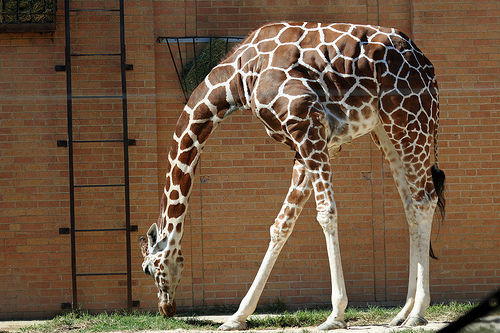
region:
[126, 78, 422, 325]
tall giraffe bending over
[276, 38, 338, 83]
brown and white spots on giraffe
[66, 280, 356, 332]
short green grass on ground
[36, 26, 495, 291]
red brick wall near giraffe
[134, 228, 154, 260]
small horns on head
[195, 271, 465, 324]
white hoofs on giraffe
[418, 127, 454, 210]
bushy black tail on giraffe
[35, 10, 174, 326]
metal ladder attached to wall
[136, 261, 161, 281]
small dark eye of giraffe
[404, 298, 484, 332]
dark object on foreground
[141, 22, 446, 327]
giraffe bending down eating the grass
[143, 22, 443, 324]
a brown and tan giraffe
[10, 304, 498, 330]
grass on the ground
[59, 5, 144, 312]
a black metal ladder on the wall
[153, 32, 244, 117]
a black feeder on the wall with grass in it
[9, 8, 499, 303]
a brick wall behind the giraffe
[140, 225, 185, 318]
the giraffe's head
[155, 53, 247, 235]
the girafffe's long neck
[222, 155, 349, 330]
the giraffe's two front legs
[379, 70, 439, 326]
the giraffe's two hind legs.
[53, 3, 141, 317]
Black iron ladder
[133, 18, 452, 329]
Brown and white giraffe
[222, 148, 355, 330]
Two front giraffe legs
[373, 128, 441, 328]
Back legs of a giraffe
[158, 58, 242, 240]
A giraffe's long neck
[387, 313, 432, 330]
Hooves of a giraffe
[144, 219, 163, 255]
Ear of a giraffe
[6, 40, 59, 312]
Red brick wall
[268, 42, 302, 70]
Brown spot on a giraffe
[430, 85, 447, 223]
Tail of a giraffe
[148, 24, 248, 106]
a giraffe feeder on a wall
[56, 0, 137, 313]
a black ladder on the side of a giraffe pen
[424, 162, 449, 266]
black hair at the end of a giraffe tail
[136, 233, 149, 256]
a black tipped horn on a giraffe head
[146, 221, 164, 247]
the ear of a giraffe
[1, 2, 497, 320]
a red brick wall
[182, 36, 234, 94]
green hay in a giraffe feeder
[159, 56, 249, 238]
the long neck of a giraffe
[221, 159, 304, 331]
a front leg extended forward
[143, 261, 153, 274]
the eye of a giraffe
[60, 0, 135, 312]
A black metal ladder on the wal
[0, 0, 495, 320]
A large brick wall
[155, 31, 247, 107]
A small basket on the wall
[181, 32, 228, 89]
some grass in the basket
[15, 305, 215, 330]
A small patch of grass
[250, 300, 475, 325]
A small patch of grass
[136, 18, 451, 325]
A grazing giraffe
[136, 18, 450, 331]
A giraffe eating some grass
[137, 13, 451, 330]
A giraffe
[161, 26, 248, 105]
A small feeding basket